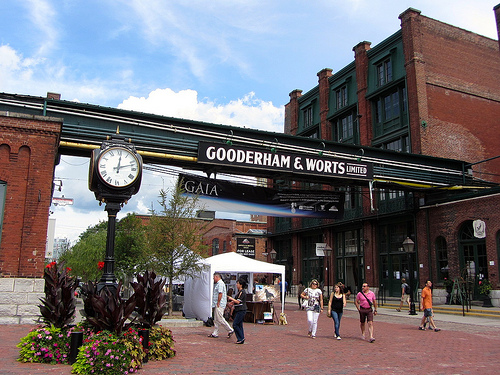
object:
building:
[267, 4, 500, 308]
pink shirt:
[356, 290, 376, 309]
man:
[355, 283, 378, 343]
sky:
[0, 0, 495, 266]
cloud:
[117, 87, 286, 133]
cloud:
[0, 42, 119, 102]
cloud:
[48, 196, 149, 251]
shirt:
[421, 286, 432, 309]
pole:
[97, 202, 121, 295]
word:
[305, 158, 345, 175]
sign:
[177, 171, 346, 219]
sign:
[197, 140, 373, 180]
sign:
[472, 219, 486, 238]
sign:
[236, 237, 255, 259]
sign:
[315, 243, 327, 257]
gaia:
[185, 181, 219, 196]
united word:
[346, 163, 367, 177]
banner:
[177, 173, 346, 219]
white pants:
[306, 308, 320, 337]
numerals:
[125, 152, 130, 158]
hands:
[117, 156, 122, 173]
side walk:
[0, 303, 498, 374]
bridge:
[0, 92, 473, 191]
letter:
[205, 146, 215, 160]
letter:
[216, 147, 226, 161]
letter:
[226, 148, 236, 162]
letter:
[236, 149, 246, 163]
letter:
[245, 151, 254, 164]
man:
[208, 272, 235, 339]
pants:
[211, 305, 234, 338]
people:
[297, 280, 305, 311]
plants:
[121, 266, 168, 325]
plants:
[87, 279, 137, 335]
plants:
[32, 259, 79, 327]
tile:
[1, 302, 499, 375]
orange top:
[421, 286, 432, 310]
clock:
[97, 147, 140, 188]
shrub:
[32, 260, 81, 328]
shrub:
[126, 323, 177, 362]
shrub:
[70, 329, 147, 375]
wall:
[419, 15, 500, 183]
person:
[300, 279, 324, 339]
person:
[326, 284, 346, 340]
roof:
[184, 252, 286, 274]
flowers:
[17, 314, 180, 375]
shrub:
[116, 269, 170, 328]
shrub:
[77, 277, 106, 317]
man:
[418, 279, 441, 332]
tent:
[133, 243, 205, 310]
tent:
[182, 252, 285, 324]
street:
[284, 297, 500, 340]